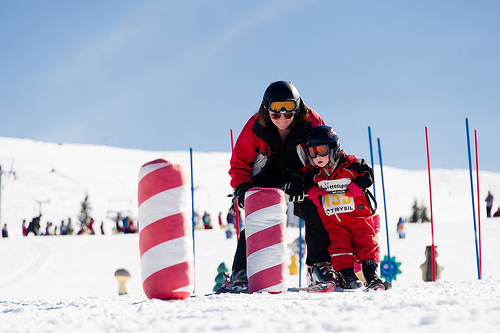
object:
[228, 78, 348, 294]
adult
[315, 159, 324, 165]
mouth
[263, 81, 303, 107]
helmet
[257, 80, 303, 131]
woman's head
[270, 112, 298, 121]
sunglasses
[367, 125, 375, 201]
pole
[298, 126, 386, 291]
child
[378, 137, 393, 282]
pole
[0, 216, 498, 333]
ground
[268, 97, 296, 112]
goggles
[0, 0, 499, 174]
sky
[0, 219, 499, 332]
snow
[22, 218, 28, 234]
people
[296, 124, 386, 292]
kid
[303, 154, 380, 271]
snowsuit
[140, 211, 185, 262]
stripes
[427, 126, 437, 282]
red pole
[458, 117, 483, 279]
stick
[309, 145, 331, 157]
eyewear